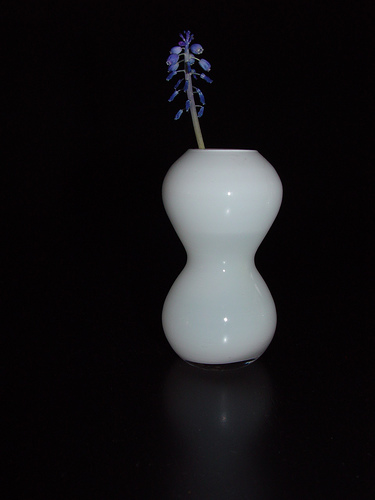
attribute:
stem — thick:
[183, 73, 205, 149]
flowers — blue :
[163, 22, 212, 126]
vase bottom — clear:
[181, 356, 251, 370]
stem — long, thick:
[185, 67, 205, 148]